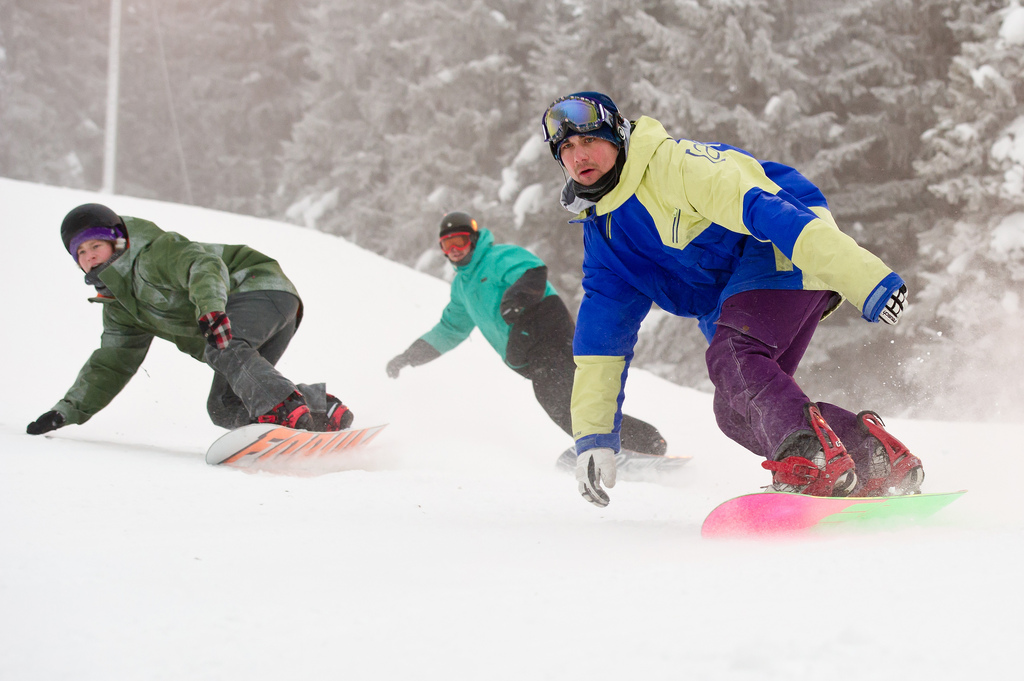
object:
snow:
[0, 188, 1021, 671]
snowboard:
[761, 404, 926, 497]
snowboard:
[258, 383, 354, 432]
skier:
[539, 92, 964, 539]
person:
[386, 214, 666, 458]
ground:
[0, 323, 1022, 679]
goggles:
[540, 95, 615, 144]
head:
[542, 91, 632, 187]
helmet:
[542, 90, 630, 166]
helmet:
[440, 212, 479, 254]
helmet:
[60, 204, 126, 256]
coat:
[50, 215, 304, 423]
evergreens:
[0, 0, 1024, 181]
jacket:
[559, 115, 909, 457]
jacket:
[403, 226, 575, 367]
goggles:
[440, 230, 476, 253]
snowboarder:
[24, 204, 355, 434]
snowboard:
[205, 422, 389, 475]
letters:
[217, 427, 386, 466]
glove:
[198, 310, 233, 350]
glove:
[28, 410, 64, 434]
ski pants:
[706, 289, 868, 461]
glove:
[575, 444, 618, 509]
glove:
[877, 284, 909, 326]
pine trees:
[624, 0, 882, 395]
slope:
[0, 224, 714, 675]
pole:
[99, 0, 123, 198]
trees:
[911, 1, 1023, 367]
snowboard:
[701, 491, 985, 540]